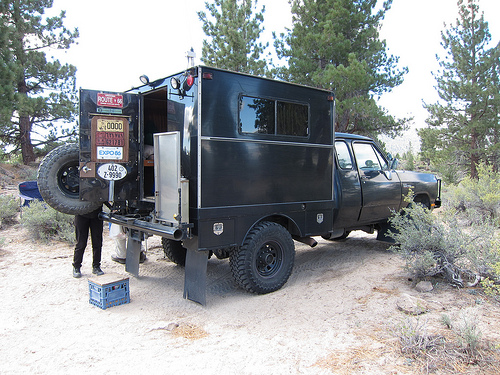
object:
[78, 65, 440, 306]
truck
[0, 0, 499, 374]
woods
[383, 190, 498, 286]
bush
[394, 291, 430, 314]
stone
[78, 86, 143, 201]
door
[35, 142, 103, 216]
tire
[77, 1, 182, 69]
sky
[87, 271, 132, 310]
crate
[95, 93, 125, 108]
plates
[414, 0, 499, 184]
tree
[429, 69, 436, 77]
leaves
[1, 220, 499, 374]
road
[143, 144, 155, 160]
merchandise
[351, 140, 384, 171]
window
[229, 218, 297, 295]
wheel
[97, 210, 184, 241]
pipe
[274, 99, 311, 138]
windows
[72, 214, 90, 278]
legs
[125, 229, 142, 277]
mudflap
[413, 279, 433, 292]
rock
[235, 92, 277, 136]
window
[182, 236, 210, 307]
mudflaps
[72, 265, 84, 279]
shoes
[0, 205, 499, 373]
ground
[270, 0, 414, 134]
trees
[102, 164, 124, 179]
logo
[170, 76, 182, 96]
lights